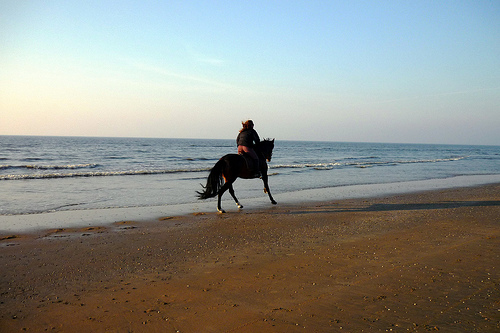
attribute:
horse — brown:
[202, 138, 282, 217]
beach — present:
[12, 218, 493, 319]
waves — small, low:
[4, 159, 186, 181]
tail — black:
[197, 165, 226, 203]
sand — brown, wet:
[15, 224, 256, 246]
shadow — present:
[276, 195, 500, 222]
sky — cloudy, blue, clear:
[6, 9, 497, 118]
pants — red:
[237, 144, 260, 160]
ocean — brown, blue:
[9, 128, 496, 189]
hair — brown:
[238, 119, 254, 132]